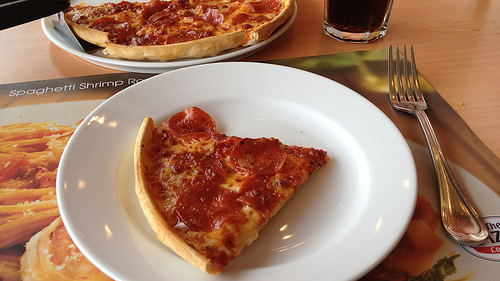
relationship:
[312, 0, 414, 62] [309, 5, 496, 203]
glass on table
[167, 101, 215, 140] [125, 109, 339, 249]
pepperoni on pizza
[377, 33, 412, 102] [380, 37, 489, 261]
tine on fork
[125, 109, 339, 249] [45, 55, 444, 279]
pizza on plate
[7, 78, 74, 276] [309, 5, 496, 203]
mat on table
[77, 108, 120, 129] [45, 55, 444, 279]
light on plate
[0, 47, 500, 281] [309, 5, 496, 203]
mat on table